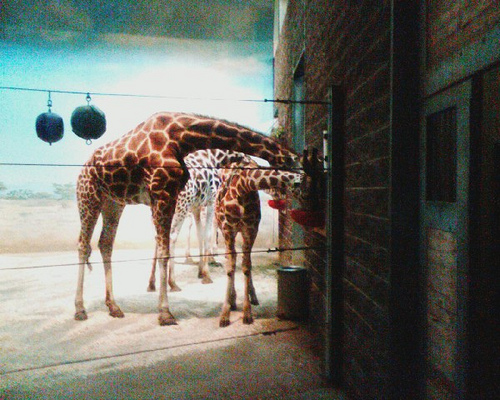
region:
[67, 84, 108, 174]
Black object hanging from wire.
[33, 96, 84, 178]
Black object hanging from wire.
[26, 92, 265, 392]
Wire fence holding giraffes in area.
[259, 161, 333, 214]
Giraffe leaning over to eat.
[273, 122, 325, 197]
Giraffe leaning over to eat.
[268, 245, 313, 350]
Round container on ground near wall.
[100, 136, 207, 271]
Giraffe is brown and white.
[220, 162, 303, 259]
Giraffe is brown and white.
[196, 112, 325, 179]
Giraffe has long neck.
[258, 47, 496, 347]
Brick building next to giraffes.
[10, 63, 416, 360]
Three giraffes feeding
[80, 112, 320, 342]
The giraffes are brown and yellow.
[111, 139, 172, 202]
The giraffes have spots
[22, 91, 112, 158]
Two feeding containers hanging from a wire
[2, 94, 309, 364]
Metal fence wires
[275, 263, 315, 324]
Watering can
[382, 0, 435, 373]
A large metal pole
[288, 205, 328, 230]
Red feeding tray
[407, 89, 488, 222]
A barred off window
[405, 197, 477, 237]
Grey metal window framing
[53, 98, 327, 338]
The giraffes are standing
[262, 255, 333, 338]
Small round grey bin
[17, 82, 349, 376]
The wires are black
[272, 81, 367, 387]
Wires attached to a grey post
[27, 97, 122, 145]
Blue ball attached to a wire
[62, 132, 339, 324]
The giraffes are eating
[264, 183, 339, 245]
The feed bins are red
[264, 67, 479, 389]
The building is brown and green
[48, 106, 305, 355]
The giraffes are on dirt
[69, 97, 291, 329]
The giraffes have spots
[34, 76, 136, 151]
Two weights hanging from a line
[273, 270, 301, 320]
Metal trash can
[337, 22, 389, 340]
Red brick wall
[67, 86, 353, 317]
Two giraffes eating from a red bucket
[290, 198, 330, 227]
Circular red feeding tray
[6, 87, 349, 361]
Fence made up of wires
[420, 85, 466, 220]
A window with bars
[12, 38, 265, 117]
Blue sky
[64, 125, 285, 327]
Two giraffes standing on sandy ground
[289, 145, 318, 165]
The horns of an adult giraffe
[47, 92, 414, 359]
Three giraffes eating food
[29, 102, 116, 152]
Two black water containers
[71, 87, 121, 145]
The container hangs from a metal wire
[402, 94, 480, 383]
A grey metal door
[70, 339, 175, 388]
Dirt beneath the giraffe's feet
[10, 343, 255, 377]
A thin metal wire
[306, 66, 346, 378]
A large metal pole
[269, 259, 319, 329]
A small grey trash can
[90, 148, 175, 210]
The giraffe has brown spots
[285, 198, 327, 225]
Red feeding trays